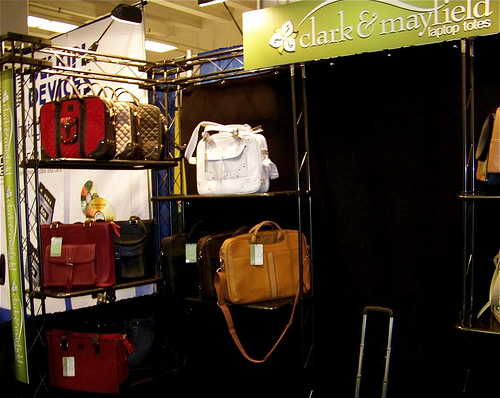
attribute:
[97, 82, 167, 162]
bag — quilted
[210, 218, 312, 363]
bag — brown, Hanging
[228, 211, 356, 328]
bag — Brown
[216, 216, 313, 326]
bag — white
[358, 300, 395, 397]
handle — Black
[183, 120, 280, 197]
bag — Hanging, white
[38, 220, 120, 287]
bag — Hanging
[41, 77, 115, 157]
bag — Hanging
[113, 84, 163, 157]
bag — Hanging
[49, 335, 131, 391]
bag — red 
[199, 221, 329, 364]
bag — light brown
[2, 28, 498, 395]
hanging shelves — silver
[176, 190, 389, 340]
bag — black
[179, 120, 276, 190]
laptop bag — Hanging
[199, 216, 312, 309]
laptop bag — Hanging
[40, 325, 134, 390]
laptop bag — Hanging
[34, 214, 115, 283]
laptop bag — Hanging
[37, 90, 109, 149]
laptop bag — Hanging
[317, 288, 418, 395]
luggage — silver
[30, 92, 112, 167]
bag — red 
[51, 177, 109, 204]
board — white 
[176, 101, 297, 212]
bag — white 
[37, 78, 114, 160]
tote bag — red, black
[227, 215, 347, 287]
this bag — tan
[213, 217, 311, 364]
brown case — leather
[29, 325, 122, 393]
bag — red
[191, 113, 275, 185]
bag — clark and mayfield, laptop, tote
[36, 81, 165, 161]
bags — laptop, tote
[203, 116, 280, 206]
bag — Hanging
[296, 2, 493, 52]
letters — white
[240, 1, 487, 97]
sign — green